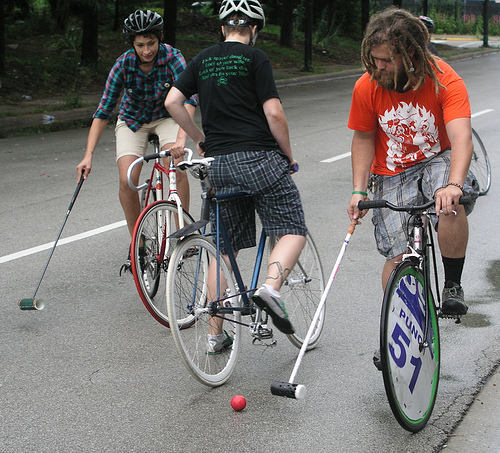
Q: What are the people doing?
A: Riding the bikes.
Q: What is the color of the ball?
A: Red.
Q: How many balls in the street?
A: One.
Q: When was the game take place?
A: Daytime.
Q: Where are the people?
A: In the street.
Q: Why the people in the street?
A: Playing.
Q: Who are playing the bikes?
A: The people.